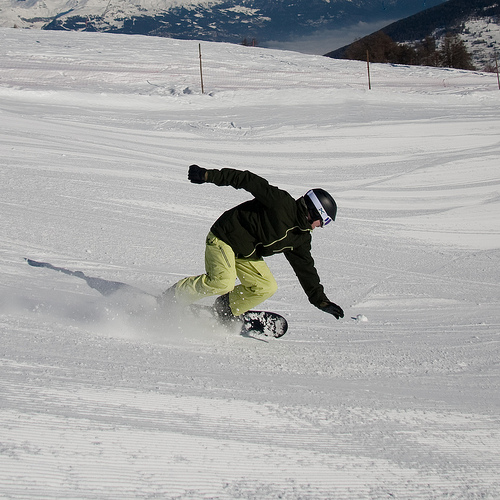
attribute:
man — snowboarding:
[162, 150, 349, 347]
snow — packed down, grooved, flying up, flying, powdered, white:
[7, 32, 499, 496]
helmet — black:
[303, 187, 340, 228]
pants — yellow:
[161, 235, 285, 327]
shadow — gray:
[33, 256, 149, 307]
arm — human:
[281, 248, 343, 320]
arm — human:
[207, 167, 282, 196]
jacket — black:
[210, 165, 321, 303]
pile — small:
[156, 84, 203, 99]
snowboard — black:
[142, 299, 286, 349]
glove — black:
[183, 162, 210, 191]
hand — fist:
[182, 164, 209, 185]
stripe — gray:
[313, 191, 328, 212]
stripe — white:
[243, 230, 290, 259]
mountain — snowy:
[316, 0, 495, 71]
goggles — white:
[306, 191, 336, 229]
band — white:
[311, 191, 324, 219]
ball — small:
[353, 312, 371, 328]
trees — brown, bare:
[354, 34, 485, 68]